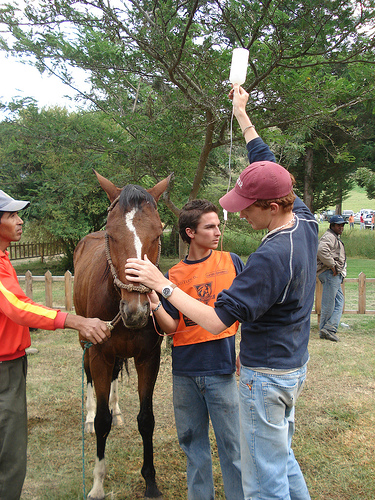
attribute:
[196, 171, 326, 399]
man — light skinned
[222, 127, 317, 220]
cap — red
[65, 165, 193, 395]
horse — brown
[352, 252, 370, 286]
grass — green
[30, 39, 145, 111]
leaves — green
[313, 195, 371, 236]
blue cap — parked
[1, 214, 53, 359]
red windbreaker — long sleeved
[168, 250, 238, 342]
vest — orange